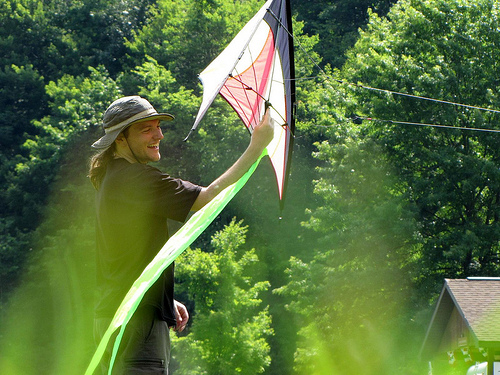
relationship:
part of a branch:
[210, 217, 253, 253] [207, 213, 250, 270]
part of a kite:
[260, 95, 293, 201] [183, 0, 296, 215]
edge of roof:
[423, 280, 448, 346] [420, 275, 499, 348]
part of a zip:
[311, 75, 432, 100] [312, 75, 500, 113]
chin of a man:
[146, 148, 162, 161] [88, 93, 274, 375]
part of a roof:
[461, 304, 500, 340] [420, 275, 499, 348]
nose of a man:
[153, 126, 163, 141] [88, 93, 274, 375]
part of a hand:
[252, 128, 275, 142] [248, 109, 275, 147]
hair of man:
[87, 140, 120, 181] [88, 93, 274, 375]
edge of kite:
[197, 0, 268, 78] [183, 0, 296, 215]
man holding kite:
[88, 93, 274, 375] [183, 0, 296, 215]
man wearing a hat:
[88, 93, 274, 375] [90, 96, 174, 151]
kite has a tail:
[183, 0, 296, 215] [89, 150, 268, 373]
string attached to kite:
[297, 107, 499, 134] [183, 0, 296, 215]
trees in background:
[192, 128, 427, 374] [0, 2, 498, 374]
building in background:
[419, 275, 500, 374] [0, 2, 498, 374]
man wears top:
[88, 93, 274, 375] [95, 156, 201, 329]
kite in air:
[183, 0, 296, 215] [2, 2, 498, 374]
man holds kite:
[88, 93, 274, 375] [183, 0, 296, 215]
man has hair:
[88, 93, 274, 375] [87, 140, 120, 181]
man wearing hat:
[88, 93, 274, 375] [90, 96, 174, 151]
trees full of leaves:
[192, 128, 427, 374] [189, 119, 429, 374]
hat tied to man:
[90, 96, 174, 151] [88, 93, 274, 375]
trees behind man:
[192, 128, 427, 374] [88, 93, 274, 375]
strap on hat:
[124, 128, 142, 164] [90, 96, 174, 151]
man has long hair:
[88, 93, 274, 375] [87, 140, 120, 181]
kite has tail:
[183, 0, 296, 215] [89, 150, 268, 373]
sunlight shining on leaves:
[43, 60, 124, 100] [44, 64, 116, 101]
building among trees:
[419, 275, 500, 374] [192, 128, 427, 374]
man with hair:
[88, 93, 274, 375] [87, 140, 120, 181]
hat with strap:
[90, 96, 174, 151] [124, 128, 142, 164]